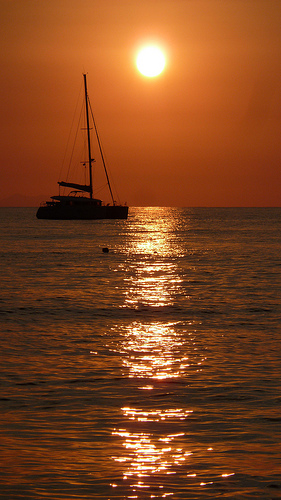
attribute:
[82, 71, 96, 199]
mast — wood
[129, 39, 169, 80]
sun — setting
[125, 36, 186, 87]
sun — yellow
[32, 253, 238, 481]
water — calm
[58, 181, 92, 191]
sail — rolled-up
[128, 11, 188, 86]
sun — yellow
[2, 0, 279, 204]
sky — orange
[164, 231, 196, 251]
water — calm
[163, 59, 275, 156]
sky — orange